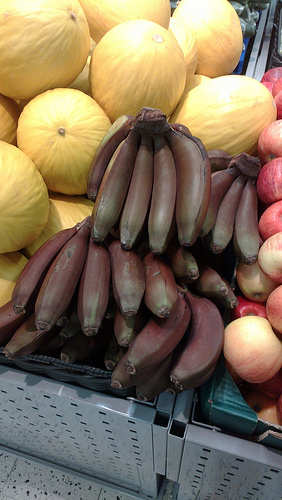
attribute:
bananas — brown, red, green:
[0, 105, 265, 406]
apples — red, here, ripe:
[223, 65, 281, 422]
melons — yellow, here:
[0, 1, 276, 304]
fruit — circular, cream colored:
[0, 1, 281, 434]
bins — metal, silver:
[0, 365, 279, 499]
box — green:
[203, 355, 280, 447]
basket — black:
[1, 337, 140, 397]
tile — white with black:
[0, 449, 151, 499]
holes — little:
[126, 409, 146, 473]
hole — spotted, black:
[200, 441, 213, 457]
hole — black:
[38, 390, 55, 401]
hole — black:
[232, 454, 248, 466]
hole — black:
[194, 467, 202, 478]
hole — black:
[10, 386, 31, 394]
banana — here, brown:
[109, 233, 148, 321]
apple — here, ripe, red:
[259, 65, 280, 120]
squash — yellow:
[166, 71, 280, 162]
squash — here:
[0, 1, 275, 311]